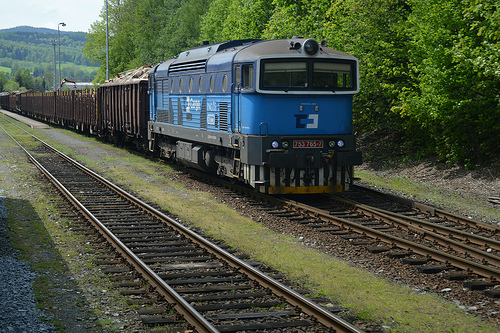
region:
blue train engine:
[159, 26, 351, 211]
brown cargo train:
[31, 80, 153, 131]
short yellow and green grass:
[7, 125, 37, 160]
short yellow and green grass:
[65, 131, 105, 173]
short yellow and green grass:
[103, 146, 135, 180]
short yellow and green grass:
[142, 158, 176, 205]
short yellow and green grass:
[170, 178, 202, 226]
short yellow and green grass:
[222, 202, 268, 255]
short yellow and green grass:
[259, 229, 316, 279]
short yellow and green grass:
[338, 268, 400, 309]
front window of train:
[260, 56, 356, 93]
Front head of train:
[239, 41, 361, 194]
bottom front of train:
[242, 135, 359, 194]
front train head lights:
[268, 139, 348, 148]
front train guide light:
[302, 38, 319, 55]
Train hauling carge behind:
[0, 63, 157, 151]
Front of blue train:
[149, 39, 361, 194]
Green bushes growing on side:
[357, 2, 497, 169]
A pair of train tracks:
[2, 117, 295, 332]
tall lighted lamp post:
[56, 20, 66, 86]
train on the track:
[111, 45, 351, 211]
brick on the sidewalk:
[158, 260, 239, 282]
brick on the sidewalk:
[148, 250, 222, 267]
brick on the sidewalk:
[198, 303, 280, 311]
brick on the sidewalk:
[196, 308, 292, 319]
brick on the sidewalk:
[362, 220, 419, 242]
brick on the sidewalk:
[352, 211, 379, 224]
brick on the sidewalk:
[341, 210, 358, 221]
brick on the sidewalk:
[116, 221, 168, 232]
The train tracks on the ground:
[68, 185, 228, 331]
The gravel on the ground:
[3, 188, 58, 328]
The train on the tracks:
[5, 28, 445, 203]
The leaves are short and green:
[388, 15, 473, 120]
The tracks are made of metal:
[105, 233, 263, 331]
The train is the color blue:
[187, 100, 349, 135]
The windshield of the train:
[263, 54, 362, 96]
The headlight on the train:
[265, 137, 291, 154]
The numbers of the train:
[290, 127, 325, 154]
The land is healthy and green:
[2, 32, 93, 77]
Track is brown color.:
[90, 200, 481, 301]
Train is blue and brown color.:
[15, 51, 305, 177]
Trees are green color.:
[355, 20, 455, 75]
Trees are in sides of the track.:
[86, 5, 458, 131]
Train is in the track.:
[196, 91, 407, 243]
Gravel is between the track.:
[300, 225, 487, 275]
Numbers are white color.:
[287, 130, 334, 161]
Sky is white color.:
[4, 4, 99, 24]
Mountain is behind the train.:
[6, 18, 131, 83]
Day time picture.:
[4, 30, 429, 329]